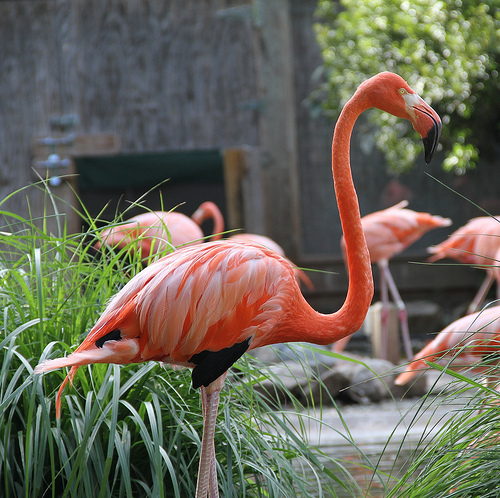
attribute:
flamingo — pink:
[90, 198, 229, 252]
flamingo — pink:
[334, 197, 454, 369]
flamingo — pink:
[428, 213, 498, 309]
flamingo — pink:
[385, 298, 499, 392]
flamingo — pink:
[25, 61, 447, 493]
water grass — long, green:
[4, 166, 282, 496]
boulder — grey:
[196, 336, 425, 408]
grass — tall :
[11, 159, 496, 496]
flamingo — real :
[54, 57, 469, 409]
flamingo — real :
[37, 70, 497, 495]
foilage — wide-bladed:
[1, 143, 343, 495]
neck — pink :
[283, 100, 418, 270]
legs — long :
[161, 367, 258, 497]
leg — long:
[377, 276, 389, 366]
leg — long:
[385, 272, 411, 360]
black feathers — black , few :
[188, 336, 250, 388]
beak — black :
[410, 123, 456, 160]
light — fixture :
[38, 140, 75, 213]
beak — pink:
[401, 99, 459, 172]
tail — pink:
[46, 279, 126, 434]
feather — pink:
[96, 265, 147, 320]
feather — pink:
[50, 342, 88, 432]